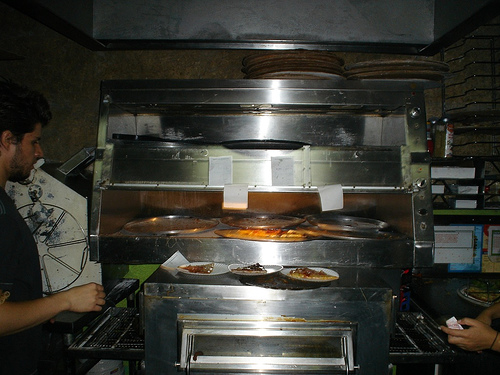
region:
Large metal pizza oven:
[58, 67, 473, 374]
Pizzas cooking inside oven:
[131, 187, 413, 317]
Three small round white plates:
[167, 235, 355, 332]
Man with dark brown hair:
[4, 80, 105, 362]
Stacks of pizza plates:
[245, 32, 459, 106]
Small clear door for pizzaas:
[164, 320, 386, 373]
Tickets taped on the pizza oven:
[174, 137, 361, 230]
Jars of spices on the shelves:
[422, 108, 466, 174]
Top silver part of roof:
[57, 0, 465, 68]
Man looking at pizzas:
[3, 85, 113, 374]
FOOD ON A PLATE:
[164, 220, 438, 374]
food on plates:
[171, 231, 496, 318]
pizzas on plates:
[161, 220, 363, 308]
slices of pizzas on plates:
[166, 235, 403, 312]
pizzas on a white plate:
[177, 229, 380, 373]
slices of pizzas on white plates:
[177, 241, 403, 308]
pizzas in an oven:
[147, 161, 401, 233]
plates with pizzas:
[148, 238, 393, 321]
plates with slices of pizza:
[179, 251, 396, 318]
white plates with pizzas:
[179, 233, 358, 290]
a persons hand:
[436, 321, 491, 351]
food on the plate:
[289, 260, 331, 282]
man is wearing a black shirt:
[7, 240, 35, 282]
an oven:
[181, 326, 345, 366]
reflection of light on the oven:
[242, 325, 280, 337]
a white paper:
[221, 185, 251, 208]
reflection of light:
[249, 115, 281, 140]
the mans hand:
[70, 288, 107, 309]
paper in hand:
[445, 316, 465, 333]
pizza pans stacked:
[258, 46, 338, 72]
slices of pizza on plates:
[170, 248, 347, 289]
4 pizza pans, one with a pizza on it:
[120, 199, 401, 254]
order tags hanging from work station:
[215, 177, 355, 217]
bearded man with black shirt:
[0, 97, 111, 345]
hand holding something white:
[435, 296, 498, 358]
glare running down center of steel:
[248, 33, 315, 373]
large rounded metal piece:
[157, 64, 371, 150]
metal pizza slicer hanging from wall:
[17, 197, 88, 299]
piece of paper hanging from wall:
[432, 219, 480, 269]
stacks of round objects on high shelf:
[238, 32, 450, 95]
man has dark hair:
[0, 90, 40, 178]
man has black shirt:
[0, 198, 72, 296]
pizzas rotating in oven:
[125, 180, 366, 290]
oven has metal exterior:
[118, 63, 360, 340]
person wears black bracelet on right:
[457, 317, 498, 361]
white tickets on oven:
[200, 147, 382, 237]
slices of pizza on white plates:
[174, 251, 344, 296]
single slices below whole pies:
[183, 237, 339, 294]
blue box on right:
[437, 218, 499, 290]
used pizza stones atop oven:
[243, 45, 450, 105]